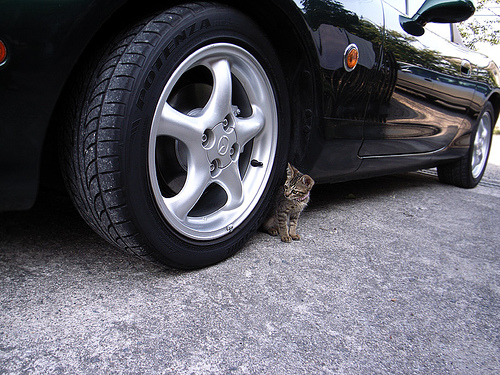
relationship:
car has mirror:
[1, 0, 500, 271] [399, 0, 476, 37]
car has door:
[1, 0, 500, 271] [358, 0, 479, 160]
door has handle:
[358, 0, 479, 160] [459, 59, 472, 78]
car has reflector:
[1, 0, 500, 271] [342, 43, 361, 72]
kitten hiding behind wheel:
[258, 163, 316, 244] [59, 1, 291, 272]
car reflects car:
[1, 0, 500, 271] [395, 60, 492, 117]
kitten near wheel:
[258, 163, 316, 244] [59, 1, 291, 272]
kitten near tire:
[258, 163, 316, 244] [437, 100, 496, 189]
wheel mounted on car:
[59, 1, 291, 272] [1, 0, 500, 271]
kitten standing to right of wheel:
[258, 163, 316, 244] [59, 1, 291, 272]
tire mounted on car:
[437, 100, 496, 189] [1, 0, 500, 271]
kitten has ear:
[258, 163, 316, 244] [286, 162, 299, 178]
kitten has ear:
[258, 163, 316, 244] [302, 174, 315, 190]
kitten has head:
[258, 163, 316, 244] [284, 162, 314, 204]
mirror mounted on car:
[399, 0, 476, 37] [1, 0, 500, 271]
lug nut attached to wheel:
[201, 133, 208, 142] [148, 43, 279, 243]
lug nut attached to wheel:
[223, 119, 230, 127] [148, 43, 279, 243]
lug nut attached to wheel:
[209, 162, 216, 173] [148, 43, 279, 243]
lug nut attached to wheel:
[229, 147, 236, 158] [148, 43, 279, 243]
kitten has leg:
[258, 163, 316, 244] [277, 209, 292, 244]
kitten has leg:
[258, 163, 316, 244] [289, 217, 300, 243]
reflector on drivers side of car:
[342, 43, 361, 72] [1, 0, 500, 271]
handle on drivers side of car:
[459, 59, 472, 78] [1, 0, 500, 271]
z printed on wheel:
[187, 22, 201, 38] [59, 1, 291, 272]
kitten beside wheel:
[258, 163, 316, 244] [59, 1, 291, 272]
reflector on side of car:
[342, 43, 361, 72] [1, 0, 500, 271]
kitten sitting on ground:
[258, 163, 316, 244] [1, 135, 499, 374]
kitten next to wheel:
[258, 163, 316, 244] [59, 1, 291, 272]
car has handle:
[1, 0, 500, 271] [459, 59, 472, 78]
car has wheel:
[1, 0, 500, 271] [59, 1, 291, 272]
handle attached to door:
[459, 59, 472, 78] [358, 0, 479, 160]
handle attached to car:
[459, 59, 472, 78] [1, 0, 500, 271]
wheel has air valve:
[59, 1, 291, 272] [250, 159, 264, 168]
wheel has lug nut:
[148, 43, 279, 243] [201, 133, 208, 142]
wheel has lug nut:
[148, 43, 279, 243] [223, 119, 230, 127]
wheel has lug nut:
[148, 43, 279, 243] [209, 162, 216, 173]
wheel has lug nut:
[148, 43, 279, 243] [229, 147, 236, 158]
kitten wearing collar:
[258, 163, 316, 244] [296, 191, 310, 203]